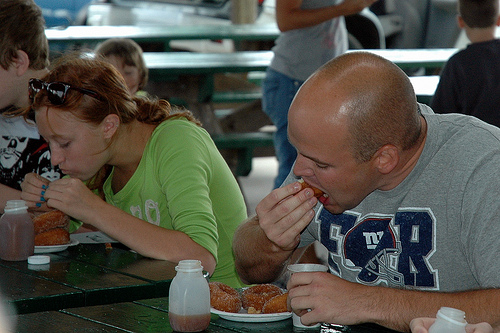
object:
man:
[230, 50, 500, 332]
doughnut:
[292, 182, 324, 198]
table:
[96, 264, 109, 274]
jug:
[168, 259, 211, 333]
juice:
[168, 311, 212, 333]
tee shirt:
[278, 102, 499, 293]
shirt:
[101, 116, 248, 289]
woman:
[19, 55, 249, 288]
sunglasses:
[26, 77, 109, 107]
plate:
[209, 308, 291, 323]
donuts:
[208, 282, 287, 314]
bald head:
[300, 79, 352, 124]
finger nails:
[35, 184, 49, 207]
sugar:
[40, 215, 56, 227]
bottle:
[0, 199, 34, 261]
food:
[28, 213, 295, 332]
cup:
[287, 262, 329, 328]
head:
[283, 50, 418, 217]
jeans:
[260, 69, 302, 190]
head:
[28, 59, 135, 181]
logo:
[313, 205, 441, 290]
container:
[425, 306, 468, 333]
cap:
[28, 255, 51, 265]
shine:
[324, 78, 367, 118]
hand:
[252, 180, 320, 248]